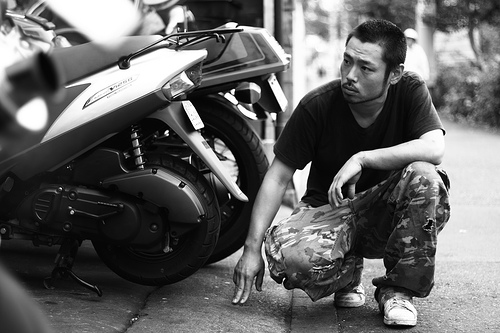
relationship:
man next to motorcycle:
[219, 2, 451, 321] [4, 21, 279, 274]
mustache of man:
[336, 80, 364, 95] [219, 2, 451, 321]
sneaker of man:
[368, 283, 420, 329] [219, 2, 451, 321]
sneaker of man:
[328, 275, 367, 308] [219, 2, 451, 321]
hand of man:
[325, 148, 373, 210] [219, 2, 451, 321]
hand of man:
[227, 245, 270, 307] [219, 2, 451, 321]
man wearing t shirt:
[219, 2, 451, 321] [262, 67, 461, 217]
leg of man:
[360, 160, 451, 301] [219, 2, 451, 321]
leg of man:
[265, 200, 364, 291] [219, 2, 451, 321]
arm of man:
[331, 82, 443, 184] [219, 2, 451, 321]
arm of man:
[221, 109, 313, 309] [219, 2, 451, 321]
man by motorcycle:
[219, 2, 451, 321] [4, 21, 279, 274]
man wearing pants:
[219, 2, 451, 321] [266, 164, 451, 296]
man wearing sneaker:
[219, 2, 451, 321] [380, 291, 416, 327]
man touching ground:
[219, 2, 451, 321] [7, 116, 497, 331]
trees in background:
[414, 5, 499, 107] [298, 64, 499, 65]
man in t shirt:
[219, 2, 451, 321] [262, 67, 461, 217]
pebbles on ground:
[211, 274, 234, 293] [7, 147, 498, 332]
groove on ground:
[112, 287, 156, 333] [7, 147, 498, 332]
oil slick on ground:
[45, 295, 65, 306] [7, 147, 498, 332]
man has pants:
[219, 2, 451, 321] [266, 164, 451, 296]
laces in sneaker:
[379, 287, 409, 308] [380, 291, 416, 327]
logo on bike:
[81, 74, 136, 107] [4, 21, 279, 274]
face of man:
[338, 47, 375, 109] [219, 2, 451, 321]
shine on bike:
[83, 37, 131, 54] [4, 21, 279, 274]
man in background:
[399, 19, 434, 79] [298, 64, 499, 65]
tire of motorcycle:
[94, 141, 240, 297] [4, 21, 279, 274]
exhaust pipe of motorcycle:
[3, 33, 71, 143] [4, 21, 279, 274]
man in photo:
[219, 2, 451, 321] [2, 3, 499, 330]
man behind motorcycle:
[219, 2, 451, 321] [4, 21, 279, 274]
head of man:
[334, 14, 412, 114] [219, 2, 451, 321]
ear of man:
[389, 62, 404, 87] [219, 2, 451, 321]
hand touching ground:
[325, 148, 373, 210] [7, 147, 498, 332]